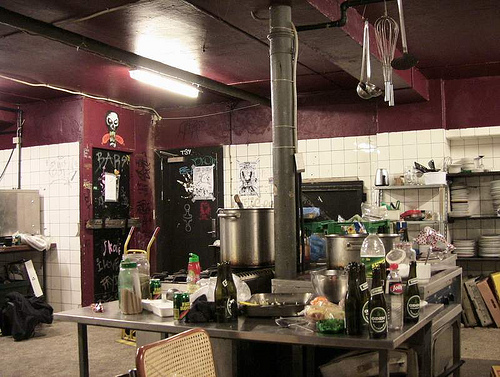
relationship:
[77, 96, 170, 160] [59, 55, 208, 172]
skull on ceiling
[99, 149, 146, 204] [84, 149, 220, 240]
graffiti on door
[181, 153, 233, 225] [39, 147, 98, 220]
poster on wall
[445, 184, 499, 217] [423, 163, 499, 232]
bowls on shelf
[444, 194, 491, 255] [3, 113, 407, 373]
plates in kitchen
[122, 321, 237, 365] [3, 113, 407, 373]
chair in kitchen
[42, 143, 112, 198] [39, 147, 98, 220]
tiles on wall